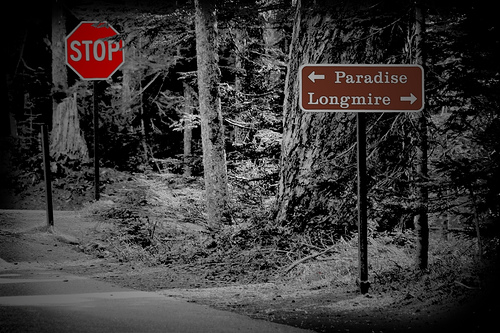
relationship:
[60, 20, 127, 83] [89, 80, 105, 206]
stop sign has pole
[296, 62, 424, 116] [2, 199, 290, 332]
sign beside street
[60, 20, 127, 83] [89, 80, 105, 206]
stop sign on top of pole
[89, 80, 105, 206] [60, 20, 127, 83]
pole has stop sign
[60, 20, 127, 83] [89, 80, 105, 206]
stop sign attached to pole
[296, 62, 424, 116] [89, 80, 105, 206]
sign on pole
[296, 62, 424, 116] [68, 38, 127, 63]
sign has letters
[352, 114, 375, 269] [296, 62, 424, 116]
post holding up sign